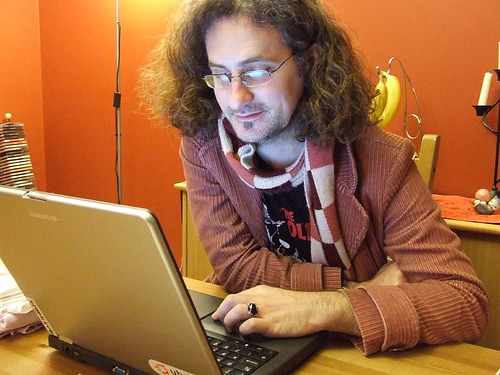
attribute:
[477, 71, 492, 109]
candle — white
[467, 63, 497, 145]
candelabra — black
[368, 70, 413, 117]
banana — yellow and ripe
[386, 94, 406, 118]
banana — bunch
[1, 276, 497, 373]
wood grain —  light brown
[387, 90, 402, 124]
banana — yellow and ripe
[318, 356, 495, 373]
wood grain — light brown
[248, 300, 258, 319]
black ring —  black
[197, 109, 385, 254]
scarf — wool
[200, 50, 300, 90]
glasses — black, framed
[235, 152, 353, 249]
scarf —  red and white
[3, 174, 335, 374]
laptop — open silver and black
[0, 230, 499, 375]
desk — wooden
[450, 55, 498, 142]
candle — white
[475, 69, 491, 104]
candle — white